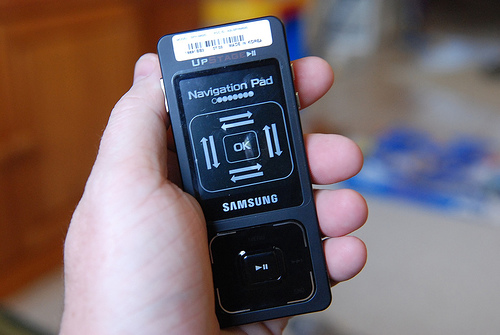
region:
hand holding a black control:
[48, 11, 373, 333]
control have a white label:
[147, 6, 337, 334]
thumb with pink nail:
[89, 34, 178, 188]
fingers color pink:
[155, 6, 383, 328]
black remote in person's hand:
[148, 12, 328, 326]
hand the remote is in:
[63, 49, 358, 334]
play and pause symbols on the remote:
[250, 259, 272, 274]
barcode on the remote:
[178, 26, 248, 49]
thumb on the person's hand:
[104, 47, 178, 185]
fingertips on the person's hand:
[289, 57, 371, 286]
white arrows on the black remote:
[190, 109, 287, 197]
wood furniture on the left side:
[7, 0, 186, 297]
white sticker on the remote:
[169, 17, 274, 59]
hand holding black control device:
[54, 17, 354, 332]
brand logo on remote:
[216, 192, 280, 212]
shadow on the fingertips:
[288, 58, 328, 281]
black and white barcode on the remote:
[168, 20, 267, 60]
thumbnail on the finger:
[129, 57, 154, 77]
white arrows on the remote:
[193, 112, 291, 189]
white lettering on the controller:
[180, 70, 277, 104]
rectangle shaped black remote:
[153, 11, 340, 334]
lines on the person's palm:
[114, 176, 209, 329]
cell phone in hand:
[150, 13, 345, 328]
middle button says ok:
[217, 123, 264, 171]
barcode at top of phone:
[179, 30, 248, 55]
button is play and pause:
[239, 245, 282, 294]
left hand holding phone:
[60, 33, 377, 333]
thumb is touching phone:
[77, 46, 169, 196]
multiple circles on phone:
[204, 86, 254, 109]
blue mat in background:
[338, 115, 493, 224]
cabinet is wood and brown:
[1, 0, 206, 296]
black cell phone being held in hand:
[148, 9, 354, 329]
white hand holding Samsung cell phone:
[53, 13, 368, 331]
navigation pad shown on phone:
[189, 72, 278, 99]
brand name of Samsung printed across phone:
[218, 188, 286, 214]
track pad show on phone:
[183, 98, 298, 190]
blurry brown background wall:
[8, 6, 205, 299]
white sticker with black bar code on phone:
[170, 20, 273, 62]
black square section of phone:
[206, 223, 314, 316]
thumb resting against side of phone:
[68, 48, 183, 324]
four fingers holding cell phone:
[288, 58, 365, 293]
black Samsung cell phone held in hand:
[158, 15, 339, 332]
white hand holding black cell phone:
[48, 9, 381, 331]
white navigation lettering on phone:
[182, 68, 282, 109]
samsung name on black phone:
[214, 190, 290, 216]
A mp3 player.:
[152, 8, 332, 320]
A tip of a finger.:
[320, 238, 365, 275]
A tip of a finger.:
[313, 182, 370, 234]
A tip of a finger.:
[301, 127, 361, 183]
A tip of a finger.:
[292, 55, 333, 105]